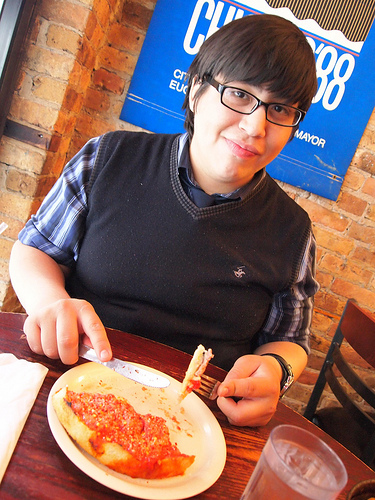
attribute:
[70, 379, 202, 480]
pizza — partially eaten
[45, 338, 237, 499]
plate — white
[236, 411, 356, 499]
cup — filled, clear, plastic, full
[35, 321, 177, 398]
knife — silver, held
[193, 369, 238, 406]
fork — held, silver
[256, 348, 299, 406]
watch — black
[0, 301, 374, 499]
table — wooden, round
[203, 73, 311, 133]
glasses — black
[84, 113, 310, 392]
vest — gray, black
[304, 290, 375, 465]
chair — wooden, wood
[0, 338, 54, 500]
napkin — white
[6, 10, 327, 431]
man — eating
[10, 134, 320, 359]
shirt — plaid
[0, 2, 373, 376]
wall — brick